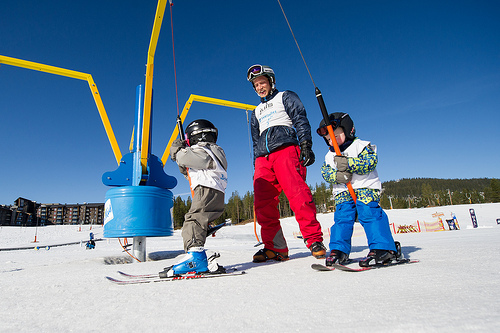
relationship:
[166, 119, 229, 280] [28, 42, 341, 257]
boy on ride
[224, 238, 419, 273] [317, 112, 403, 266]
shadows on boy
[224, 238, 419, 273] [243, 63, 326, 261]
shadows on man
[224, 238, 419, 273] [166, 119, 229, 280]
shadows on boy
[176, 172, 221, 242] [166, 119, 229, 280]
pants of boy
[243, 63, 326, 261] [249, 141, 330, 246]
man wearing pants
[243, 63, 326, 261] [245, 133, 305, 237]
man wearing pants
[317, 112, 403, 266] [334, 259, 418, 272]
boy wearing ski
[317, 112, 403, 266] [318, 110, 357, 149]
boy has on helmet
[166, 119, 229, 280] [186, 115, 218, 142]
boy has on helmet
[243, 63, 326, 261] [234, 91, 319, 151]
man wearing jacket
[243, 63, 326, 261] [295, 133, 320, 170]
man wearing glove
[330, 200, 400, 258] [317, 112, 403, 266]
blue pants of boy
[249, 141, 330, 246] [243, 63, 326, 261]
pants of man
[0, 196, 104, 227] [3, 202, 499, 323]
building on mountain top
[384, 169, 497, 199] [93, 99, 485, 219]
mountain in back ground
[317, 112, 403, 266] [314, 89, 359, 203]
boy holding pole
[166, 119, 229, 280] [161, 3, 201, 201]
boy holding pole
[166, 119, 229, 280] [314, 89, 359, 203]
boy holding pole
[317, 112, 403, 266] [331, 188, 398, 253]
boy wearing blue pants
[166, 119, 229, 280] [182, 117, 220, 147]
boy wearing helmet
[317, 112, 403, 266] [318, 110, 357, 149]
boy wearing helmet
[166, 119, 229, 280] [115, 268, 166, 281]
boy wearing ski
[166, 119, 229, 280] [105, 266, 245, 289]
boy wearing ski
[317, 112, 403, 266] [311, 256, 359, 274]
boy wearing ski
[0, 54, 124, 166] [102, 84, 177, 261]
pole sticking out of base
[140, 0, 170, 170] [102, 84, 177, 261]
pole sticking out of base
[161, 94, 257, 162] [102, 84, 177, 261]
pole sticking out of base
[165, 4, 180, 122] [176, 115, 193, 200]
wire extending from pole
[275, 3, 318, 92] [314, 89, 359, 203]
wire extending from pole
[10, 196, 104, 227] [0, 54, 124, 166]
building behind pole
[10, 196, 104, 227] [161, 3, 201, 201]
building behind pole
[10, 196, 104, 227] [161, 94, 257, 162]
building behind pole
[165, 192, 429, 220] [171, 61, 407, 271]
trees behind family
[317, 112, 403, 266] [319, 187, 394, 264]
boy wearing pants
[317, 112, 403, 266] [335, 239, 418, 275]
boy wearing ski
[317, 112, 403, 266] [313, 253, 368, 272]
boy wearing ski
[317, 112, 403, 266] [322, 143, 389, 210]
boy wearing jacket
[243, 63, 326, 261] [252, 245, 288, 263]
man wearing shoe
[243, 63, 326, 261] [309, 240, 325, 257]
man wearing shoe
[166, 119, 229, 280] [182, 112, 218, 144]
boy wearing helmet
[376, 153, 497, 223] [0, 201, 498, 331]
mountains behind slope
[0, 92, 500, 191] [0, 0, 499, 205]
cloud in sky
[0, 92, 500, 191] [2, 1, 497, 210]
cloud in blue sky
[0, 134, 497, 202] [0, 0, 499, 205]
cloud in sky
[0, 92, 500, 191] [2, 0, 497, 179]
cloud in sky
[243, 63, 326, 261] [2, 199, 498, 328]
man standing in snow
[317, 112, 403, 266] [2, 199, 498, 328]
boy standing in snow